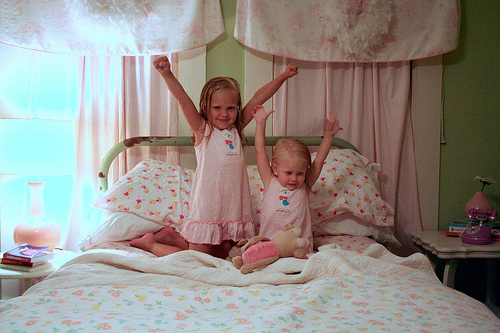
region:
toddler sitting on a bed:
[249, 103, 343, 273]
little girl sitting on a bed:
[116, 56, 296, 263]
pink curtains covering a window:
[238, 0, 459, 257]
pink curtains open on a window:
[1, 4, 208, 215]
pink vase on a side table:
[12, 180, 57, 253]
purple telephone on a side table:
[460, 206, 490, 243]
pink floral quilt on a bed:
[0, 244, 497, 329]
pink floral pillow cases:
[235, 148, 392, 227]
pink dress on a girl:
[177, 122, 253, 242]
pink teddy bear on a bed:
[229, 220, 309, 274]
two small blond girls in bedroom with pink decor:
[1, 0, 499, 331]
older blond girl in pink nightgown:
[131, 56, 257, 260]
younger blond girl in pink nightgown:
[251, 100, 343, 255]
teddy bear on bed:
[228, 226, 313, 276]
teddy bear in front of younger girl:
[227, 102, 343, 274]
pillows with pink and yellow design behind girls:
[95, 147, 396, 234]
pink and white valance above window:
[235, 0, 465, 227]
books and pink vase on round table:
[0, 177, 79, 279]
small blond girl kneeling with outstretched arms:
[127, 55, 297, 257]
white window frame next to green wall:
[410, 0, 499, 230]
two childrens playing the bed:
[129, 33, 361, 307]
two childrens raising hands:
[151, 45, 364, 220]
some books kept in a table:
[1, 231, 58, 290]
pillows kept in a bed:
[114, 148, 416, 248]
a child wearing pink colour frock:
[179, 113, 254, 250]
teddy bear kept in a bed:
[230, 225, 327, 281]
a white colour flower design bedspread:
[73, 274, 428, 331]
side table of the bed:
[407, 211, 499, 283]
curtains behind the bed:
[53, 3, 478, 220]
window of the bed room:
[0, 3, 159, 208]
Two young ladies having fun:
[90, 21, 410, 301]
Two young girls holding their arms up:
[125, 40, 385, 305]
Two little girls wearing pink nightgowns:
[130, 31, 360, 291]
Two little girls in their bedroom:
[126, 35, 381, 300]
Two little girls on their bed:
[130, 30, 370, 290]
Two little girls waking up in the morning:
[90, 35, 390, 295]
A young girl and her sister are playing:
[75, 45, 412, 305]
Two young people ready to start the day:
[106, 11, 387, 302]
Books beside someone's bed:
[0, 243, 51, 268]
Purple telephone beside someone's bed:
[464, 208, 496, 248]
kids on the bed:
[123, 34, 335, 279]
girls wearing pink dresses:
[147, 86, 383, 306]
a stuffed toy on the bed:
[186, 203, 374, 291]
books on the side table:
[8, 228, 85, 294]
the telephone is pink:
[445, 194, 493, 256]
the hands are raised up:
[145, 21, 357, 303]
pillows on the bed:
[87, 128, 439, 260]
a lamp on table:
[4, 105, 109, 325]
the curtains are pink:
[58, 2, 428, 272]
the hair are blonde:
[198, 63, 343, 205]